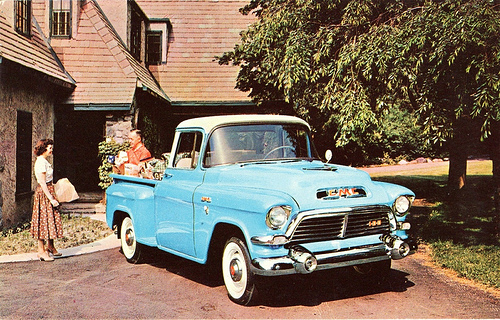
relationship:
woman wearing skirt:
[31, 138, 65, 262] [31, 182, 64, 239]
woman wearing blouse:
[31, 138, 65, 262] [34, 155, 53, 182]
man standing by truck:
[113, 129, 153, 176] [107, 114, 417, 307]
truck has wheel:
[107, 114, 417, 307] [350, 260, 391, 279]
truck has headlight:
[107, 114, 417, 307] [394, 196, 412, 216]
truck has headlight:
[107, 114, 417, 307] [268, 206, 288, 229]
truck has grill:
[107, 114, 417, 307] [251, 204, 410, 246]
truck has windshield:
[107, 114, 417, 307] [203, 123, 320, 167]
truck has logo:
[107, 114, 417, 307] [327, 186, 361, 197]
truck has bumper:
[107, 114, 417, 307] [252, 235, 418, 276]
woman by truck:
[31, 138, 65, 262] [107, 114, 417, 307]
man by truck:
[113, 129, 153, 176] [107, 114, 417, 307]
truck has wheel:
[107, 114, 417, 307] [221, 236, 274, 305]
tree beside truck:
[211, 1, 500, 199] [107, 114, 417, 307]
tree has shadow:
[211, 1, 500, 199] [370, 174, 500, 247]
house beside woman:
[1, 0, 293, 232] [31, 138, 65, 262]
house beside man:
[1, 0, 293, 232] [113, 129, 153, 176]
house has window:
[1, 0, 293, 232] [148, 35, 161, 62]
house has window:
[1, 0, 293, 232] [132, 15, 140, 60]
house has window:
[1, 0, 293, 232] [52, 0, 71, 37]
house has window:
[1, 0, 293, 232] [16, 1, 28, 35]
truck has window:
[107, 114, 417, 307] [172, 130, 202, 170]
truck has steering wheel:
[107, 114, 417, 307] [264, 146, 298, 159]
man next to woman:
[113, 129, 153, 176] [31, 138, 65, 262]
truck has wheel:
[107, 114, 417, 307] [221, 236, 258, 307]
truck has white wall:
[107, 114, 417, 307] [120, 217, 137, 259]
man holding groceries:
[113, 129, 153, 176] [113, 150, 130, 174]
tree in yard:
[211, 1, 500, 199] [338, 149, 500, 299]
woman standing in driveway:
[31, 138, 65, 262] [0, 244, 499, 319]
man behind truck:
[113, 129, 153, 176] [107, 114, 417, 307]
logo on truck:
[327, 186, 361, 197] [107, 114, 417, 307]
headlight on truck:
[394, 196, 412, 216] [107, 114, 417, 307]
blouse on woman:
[34, 155, 53, 182] [31, 138, 65, 262]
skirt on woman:
[31, 182, 64, 239] [31, 138, 65, 262]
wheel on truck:
[350, 260, 391, 279] [107, 114, 417, 307]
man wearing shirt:
[113, 129, 153, 176] [126, 144, 152, 165]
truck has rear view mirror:
[107, 114, 417, 307] [326, 148, 334, 163]